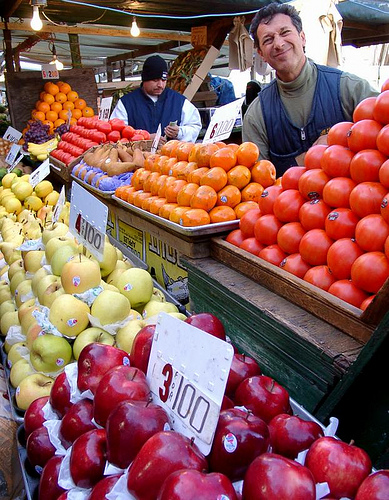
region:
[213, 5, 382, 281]
a happy man working at a fruit market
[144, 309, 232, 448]
a sign on the apples priced at 3 for 1.00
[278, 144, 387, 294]
a large display of tomatoes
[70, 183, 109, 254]
a sign on the yellow apples selling them for 4 for 1.00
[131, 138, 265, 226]
a large tower of oranges stacked on top of each other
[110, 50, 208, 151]
a man with a black knit cap handling money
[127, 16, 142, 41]
a bare light bulb hanging from the ceiling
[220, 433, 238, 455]
oval white sticker on one of the red apples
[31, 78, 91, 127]
a large tower of stacked oranges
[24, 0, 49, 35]
a light bulb hanging from the ceiling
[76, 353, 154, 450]
the apples are shiny and red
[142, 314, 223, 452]
the sign says 3 for 1.00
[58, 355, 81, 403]
the apples are sitting on white paper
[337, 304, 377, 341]
the tomatoes are stacked in a brown case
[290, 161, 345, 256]
the tomatoes are an orange-red color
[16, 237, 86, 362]
the yellow apples are next to the red apples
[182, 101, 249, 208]
the oranges are 6 for 1.00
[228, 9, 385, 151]
the man is smiling behind the oranges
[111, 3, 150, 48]
the light bulb is hanging on a wire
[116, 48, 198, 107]
the man is wearing a black knitted cap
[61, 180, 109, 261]
white sign with red lettering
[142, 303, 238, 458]
white sign with red lettering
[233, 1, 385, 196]
man in gray shirt and blue vest behind fruit stand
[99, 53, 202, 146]
man wearing black hat and blue vest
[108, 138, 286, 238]
large pile of oranges on a metal tray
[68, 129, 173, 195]
large pile of pears on a metal tray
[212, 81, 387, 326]
large pile of tomatoes in a wooden container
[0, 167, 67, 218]
large pile of lemons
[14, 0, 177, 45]
lightbulbs glowing above fruit stand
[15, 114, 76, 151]
pile of purple grapes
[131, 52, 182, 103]
a man wearing a blue hat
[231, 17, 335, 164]
a man wearing a blue vest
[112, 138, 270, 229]
several oranges in a stack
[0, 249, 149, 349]
several yellow apples in a stack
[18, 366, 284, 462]
several red apples in a stack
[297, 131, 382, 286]
several tomatoes in a stack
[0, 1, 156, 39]
two light bulbs hanging from the cieling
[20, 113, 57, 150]
a stack of purple grapes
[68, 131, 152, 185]
a stack of sweet potatoes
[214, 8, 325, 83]
a man with dark hair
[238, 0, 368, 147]
middle aged man standing behind oranges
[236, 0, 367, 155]
middle aged man wearing blue vest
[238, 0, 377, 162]
middle aged man smiling at camera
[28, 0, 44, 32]
light bulb hanging from roof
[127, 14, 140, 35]
light bulb hanging from roof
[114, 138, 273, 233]
huge silver tray of florida oranges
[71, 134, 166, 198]
huge silver tray of pears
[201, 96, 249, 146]
small white sign above oranges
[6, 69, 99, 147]
wooden board behind pile of oranges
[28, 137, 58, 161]
a bunch of yellow bananas